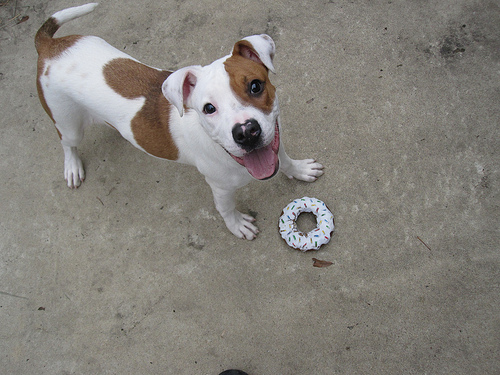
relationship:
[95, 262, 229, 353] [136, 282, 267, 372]
part of ground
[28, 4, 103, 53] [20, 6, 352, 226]
tail of dog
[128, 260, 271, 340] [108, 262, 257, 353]
surface of ground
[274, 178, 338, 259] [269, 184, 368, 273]
donut laying on ground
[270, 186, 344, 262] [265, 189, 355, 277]
frosting on donut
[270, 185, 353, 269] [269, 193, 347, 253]
sprinkles on frosting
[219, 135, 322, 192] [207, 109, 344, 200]
tongue in mouth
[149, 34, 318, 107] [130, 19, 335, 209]
ears on dog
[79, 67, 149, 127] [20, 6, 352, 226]
fur on dog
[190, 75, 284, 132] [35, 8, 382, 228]
eye of dog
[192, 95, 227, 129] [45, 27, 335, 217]
eye of dog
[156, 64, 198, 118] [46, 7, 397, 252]
ears of dog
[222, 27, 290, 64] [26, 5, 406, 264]
ear of dog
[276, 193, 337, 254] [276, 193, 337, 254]
donut like donut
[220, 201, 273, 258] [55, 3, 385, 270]
paw of dog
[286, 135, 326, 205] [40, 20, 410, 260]
paw of dog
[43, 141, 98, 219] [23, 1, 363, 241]
paw of dog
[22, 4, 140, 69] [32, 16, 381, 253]
tail of dog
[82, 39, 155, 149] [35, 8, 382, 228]
spot on dog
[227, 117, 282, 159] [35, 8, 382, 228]
nose of dog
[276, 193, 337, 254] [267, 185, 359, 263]
donut shaped toy